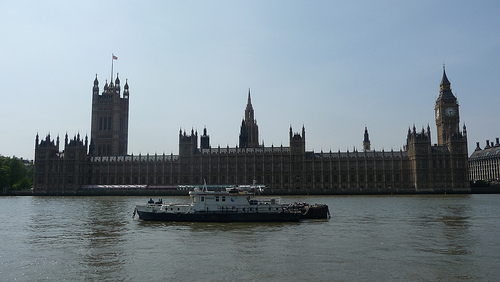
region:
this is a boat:
[128, 167, 354, 258]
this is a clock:
[415, 70, 477, 133]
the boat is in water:
[97, 162, 347, 258]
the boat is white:
[170, 174, 284, 213]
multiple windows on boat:
[176, 190, 297, 218]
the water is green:
[10, 165, 460, 277]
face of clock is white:
[439, 96, 460, 131]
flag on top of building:
[96, 35, 144, 67]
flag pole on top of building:
[105, 58, 117, 79]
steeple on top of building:
[228, 75, 265, 126]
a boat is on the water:
[137, 182, 332, 226]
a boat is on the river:
[135, 186, 336, 223]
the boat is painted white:
[139, 188, 327, 210]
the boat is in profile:
[138, 177, 330, 231]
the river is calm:
[7, 192, 498, 278]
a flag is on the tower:
[110, 52, 119, 62]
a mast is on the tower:
[107, 51, 119, 78]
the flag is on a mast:
[107, 53, 116, 76]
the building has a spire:
[240, 87, 256, 105]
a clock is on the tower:
[447, 107, 458, 117]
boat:
[124, 182, 322, 230]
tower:
[80, 56, 134, 160]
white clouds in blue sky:
[315, 86, 342, 117]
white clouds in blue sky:
[174, 42, 216, 93]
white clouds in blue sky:
[332, 65, 363, 95]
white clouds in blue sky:
[245, 8, 300, 62]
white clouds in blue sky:
[165, 65, 232, 106]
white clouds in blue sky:
[108, 35, 198, 73]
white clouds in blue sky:
[30, 25, 72, 50]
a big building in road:
[23, 48, 496, 192]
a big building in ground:
[44, 53, 493, 169]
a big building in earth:
[9, 33, 496, 175]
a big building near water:
[15, 38, 498, 214]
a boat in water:
[122, 156, 352, 234]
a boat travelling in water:
[86, 149, 342, 227]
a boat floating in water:
[96, 155, 353, 277]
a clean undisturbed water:
[63, 201, 253, 265]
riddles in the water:
[403, 224, 467, 255]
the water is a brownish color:
[39, 212, 132, 274]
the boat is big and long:
[122, 179, 332, 224]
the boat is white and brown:
[136, 196, 341, 224]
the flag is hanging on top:
[102, 55, 133, 80]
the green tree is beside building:
[5, 160, 35, 195]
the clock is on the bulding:
[441, 96, 461, 121]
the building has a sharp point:
[230, 90, 260, 115]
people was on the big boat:
[145, 195, 170, 205]